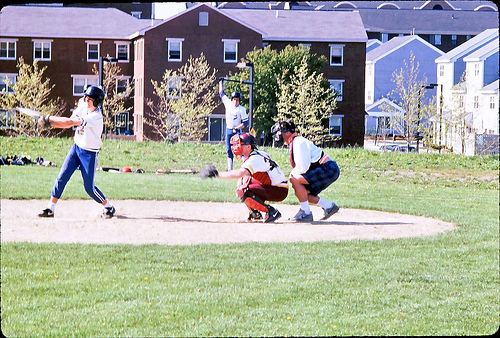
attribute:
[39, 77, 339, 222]
kids — playing, young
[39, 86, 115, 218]
kid — batting, swinging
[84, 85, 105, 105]
helmet — black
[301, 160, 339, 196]
shorts — blue, black, checkered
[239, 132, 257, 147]
helmet — red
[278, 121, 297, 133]
helmet — black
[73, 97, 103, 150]
shirt — white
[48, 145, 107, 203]
pants — blue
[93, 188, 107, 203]
stripes — white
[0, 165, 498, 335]
grass — green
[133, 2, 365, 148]
building — red, distant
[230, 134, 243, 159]
mask — red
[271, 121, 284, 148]
mask — black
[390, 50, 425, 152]
tree — white